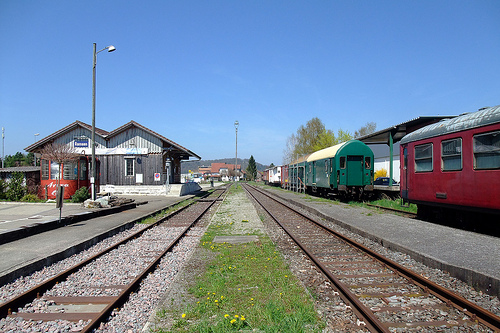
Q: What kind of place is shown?
A: It is a railroad.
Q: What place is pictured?
A: It is a railroad.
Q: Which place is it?
A: It is a railroad.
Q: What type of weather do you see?
A: It is clear.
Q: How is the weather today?
A: It is clear.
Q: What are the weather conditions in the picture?
A: It is clear.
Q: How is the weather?
A: It is clear.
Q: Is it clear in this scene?
A: Yes, it is clear.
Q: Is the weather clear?
A: Yes, it is clear.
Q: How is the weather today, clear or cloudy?
A: It is clear.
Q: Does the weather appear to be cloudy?
A: No, it is clear.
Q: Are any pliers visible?
A: No, there are no pliers.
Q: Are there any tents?
A: No, there are no tents.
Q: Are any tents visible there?
A: No, there are no tents.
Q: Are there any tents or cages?
A: No, there are no tents or cages.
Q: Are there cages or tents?
A: No, there are no tents or cages.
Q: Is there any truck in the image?
A: No, there are no trucks.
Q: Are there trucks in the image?
A: No, there are no trucks.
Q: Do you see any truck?
A: No, there are no trucks.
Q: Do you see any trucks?
A: No, there are no trucks.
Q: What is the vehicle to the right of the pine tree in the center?
A: The vehicle is a train car.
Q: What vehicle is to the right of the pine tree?
A: The vehicle is a train car.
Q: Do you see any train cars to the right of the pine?
A: Yes, there is a train car to the right of the pine.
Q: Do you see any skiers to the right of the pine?
A: No, there is a train car to the right of the pine.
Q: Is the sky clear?
A: Yes, the sky is clear.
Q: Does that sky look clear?
A: Yes, the sky is clear.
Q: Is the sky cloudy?
A: No, the sky is clear.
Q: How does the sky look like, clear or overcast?
A: The sky is clear.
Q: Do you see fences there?
A: No, there are no fences.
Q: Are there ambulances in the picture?
A: No, there are no ambulances.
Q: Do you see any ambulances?
A: No, there are no ambulances.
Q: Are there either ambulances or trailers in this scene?
A: No, there are no ambulances or trailers.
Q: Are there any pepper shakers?
A: No, there are no pepper shakers.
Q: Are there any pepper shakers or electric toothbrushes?
A: No, there are no pepper shakers or electric toothbrushes.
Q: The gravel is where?
A: The gravel is on the railroad.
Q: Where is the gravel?
A: The gravel is on the railroad.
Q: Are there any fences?
A: No, there are no fences.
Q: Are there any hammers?
A: No, there are no hammers.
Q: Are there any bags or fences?
A: No, there are no fences or bags.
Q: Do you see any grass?
A: Yes, there is grass.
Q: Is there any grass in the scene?
A: Yes, there is grass.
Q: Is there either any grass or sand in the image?
A: Yes, there is grass.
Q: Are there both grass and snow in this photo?
A: No, there is grass but no snow.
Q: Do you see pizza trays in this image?
A: No, there are no pizza trays.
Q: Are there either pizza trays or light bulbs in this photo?
A: No, there are no pizza trays or light bulbs.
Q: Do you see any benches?
A: No, there are no benches.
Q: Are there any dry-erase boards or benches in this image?
A: No, there are no benches or dry-erase boards.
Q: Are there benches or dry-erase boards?
A: No, there are no benches or dry-erase boards.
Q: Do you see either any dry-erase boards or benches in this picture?
A: No, there are no benches or dry-erase boards.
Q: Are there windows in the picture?
A: Yes, there are windows.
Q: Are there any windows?
A: Yes, there are windows.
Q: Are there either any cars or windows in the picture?
A: Yes, there are windows.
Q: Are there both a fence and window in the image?
A: No, there are windows but no fences.